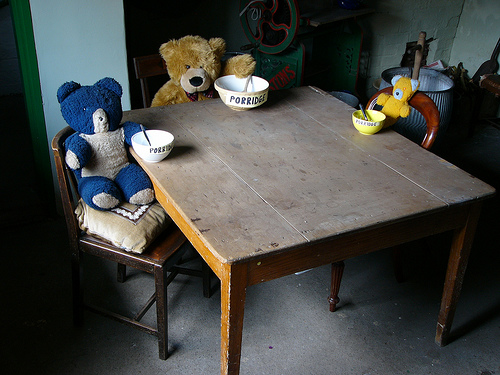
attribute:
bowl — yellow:
[351, 109, 388, 136]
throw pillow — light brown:
[73, 195, 170, 255]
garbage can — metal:
[377, 65, 456, 136]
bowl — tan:
[213, 74, 271, 113]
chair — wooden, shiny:
[363, 85, 442, 151]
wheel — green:
[238, 0, 301, 56]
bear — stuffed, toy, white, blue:
[56, 77, 155, 212]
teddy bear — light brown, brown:
[150, 34, 257, 106]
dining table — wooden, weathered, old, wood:
[121, 83, 497, 374]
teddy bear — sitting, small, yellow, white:
[376, 74, 420, 131]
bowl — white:
[130, 129, 174, 164]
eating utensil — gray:
[139, 123, 154, 148]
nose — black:
[188, 76, 204, 88]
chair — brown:
[50, 125, 212, 360]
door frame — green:
[9, 0, 58, 224]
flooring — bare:
[3, 230, 498, 375]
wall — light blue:
[28, 0, 132, 215]